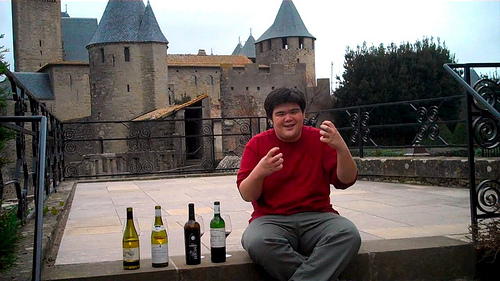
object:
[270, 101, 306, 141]
face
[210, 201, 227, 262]
glass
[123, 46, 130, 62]
windows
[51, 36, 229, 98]
castle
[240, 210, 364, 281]
pants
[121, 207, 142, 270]
bottle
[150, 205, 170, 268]
bottle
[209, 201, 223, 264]
bottle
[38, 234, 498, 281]
step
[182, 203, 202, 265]
bottle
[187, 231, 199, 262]
wine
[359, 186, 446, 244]
lines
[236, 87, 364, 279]
man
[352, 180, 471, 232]
platform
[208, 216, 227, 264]
side